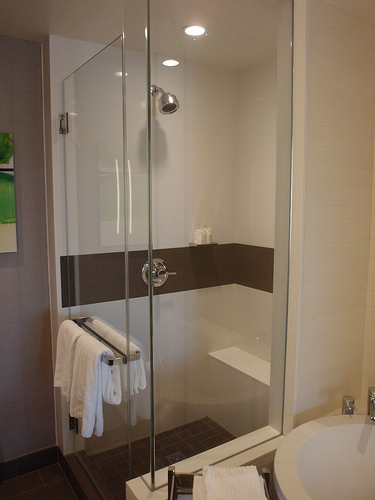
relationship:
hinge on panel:
[60, 108, 69, 134] [60, 29, 125, 480]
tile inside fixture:
[89, 415, 236, 497] [150, 84, 179, 116]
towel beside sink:
[189, 462, 266, 499] [271, 411, 373, 499]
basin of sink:
[327, 471, 374, 499] [271, 411, 373, 499]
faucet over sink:
[365, 384, 374, 422] [271, 411, 373, 499]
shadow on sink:
[356, 416, 375, 453] [271, 411, 373, 499]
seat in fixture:
[205, 347, 269, 437] [150, 84, 179, 116]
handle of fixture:
[73, 318, 118, 369] [150, 84, 179, 116]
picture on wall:
[1, 133, 15, 251] [1, 37, 55, 458]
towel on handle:
[70, 330, 120, 439] [73, 318, 118, 369]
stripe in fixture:
[61, 242, 282, 308] [150, 84, 179, 116]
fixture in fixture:
[150, 82, 179, 115] [150, 84, 179, 116]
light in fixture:
[163, 57, 178, 69] [150, 84, 179, 116]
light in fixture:
[183, 23, 204, 38] [150, 84, 179, 116]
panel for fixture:
[60, 29, 125, 480] [150, 84, 179, 116]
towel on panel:
[48, 316, 82, 398] [60, 29, 125, 480]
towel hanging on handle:
[70, 330, 120, 439] [73, 318, 118, 369]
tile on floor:
[89, 415, 236, 497] [1, 462, 75, 499]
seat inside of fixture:
[205, 347, 269, 437] [150, 84, 179, 116]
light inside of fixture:
[163, 57, 178, 69] [150, 84, 179, 116]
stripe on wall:
[61, 242, 282, 308] [1, 37, 55, 458]